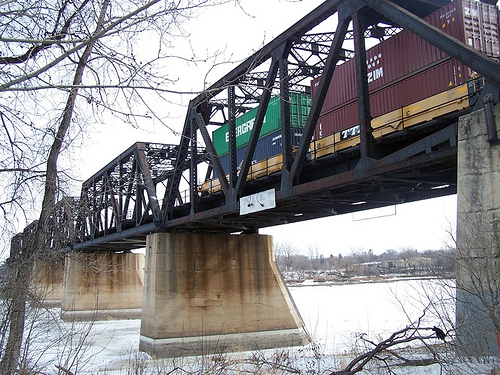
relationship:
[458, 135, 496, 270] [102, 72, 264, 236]
pillars holding up bridge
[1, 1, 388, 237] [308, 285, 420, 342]
sky above snow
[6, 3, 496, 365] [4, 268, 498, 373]
bridge over river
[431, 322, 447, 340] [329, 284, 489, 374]
object in branches